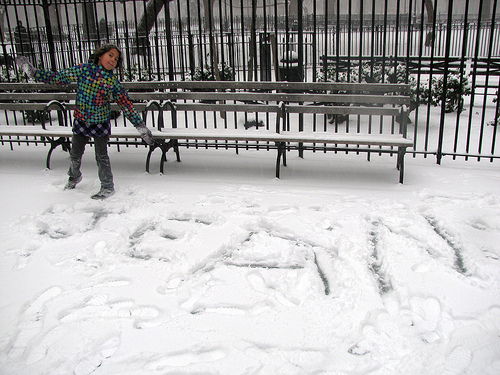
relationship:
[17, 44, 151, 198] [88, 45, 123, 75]
girl has hair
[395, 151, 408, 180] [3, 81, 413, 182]
leg on bench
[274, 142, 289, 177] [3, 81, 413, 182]
leg on bench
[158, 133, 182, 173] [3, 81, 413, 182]
leg on bench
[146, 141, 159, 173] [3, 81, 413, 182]
leg on bench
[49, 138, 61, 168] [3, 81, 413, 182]
leg on bench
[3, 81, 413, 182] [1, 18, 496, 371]
bench on snow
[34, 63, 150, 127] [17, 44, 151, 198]
jacket on girl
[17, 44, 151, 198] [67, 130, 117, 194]
girl wearing jeans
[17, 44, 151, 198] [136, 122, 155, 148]
girl has hand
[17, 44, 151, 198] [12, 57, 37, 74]
girl has hand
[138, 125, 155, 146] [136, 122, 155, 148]
glove on hand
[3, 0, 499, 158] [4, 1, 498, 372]
fence in park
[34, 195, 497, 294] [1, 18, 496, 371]
name in snow